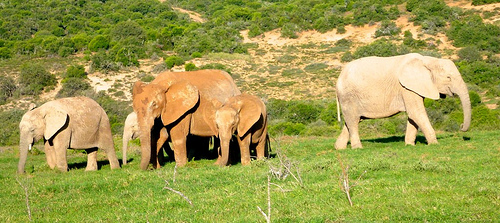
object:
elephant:
[128, 68, 244, 172]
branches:
[447, 58, 500, 89]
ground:
[0, 131, 500, 223]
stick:
[262, 173, 276, 222]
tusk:
[26, 144, 36, 151]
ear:
[43, 107, 70, 140]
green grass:
[0, 130, 500, 223]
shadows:
[69, 157, 134, 167]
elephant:
[333, 52, 474, 150]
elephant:
[15, 96, 120, 176]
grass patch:
[274, 53, 298, 64]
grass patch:
[301, 63, 328, 71]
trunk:
[456, 83, 470, 131]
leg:
[236, 131, 256, 163]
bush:
[85, 36, 112, 51]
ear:
[159, 79, 202, 126]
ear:
[236, 98, 263, 138]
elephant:
[209, 95, 272, 168]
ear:
[393, 57, 444, 101]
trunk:
[16, 132, 35, 175]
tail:
[334, 88, 343, 124]